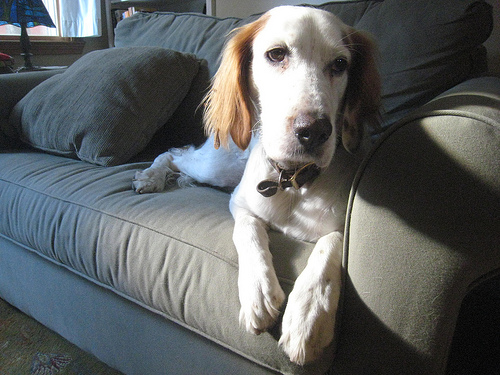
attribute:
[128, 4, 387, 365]
dog — staring, melancholy looking, white, sad looking, white-faced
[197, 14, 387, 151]
ears — floppy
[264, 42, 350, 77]
eyes — brown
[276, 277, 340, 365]
paw — dog's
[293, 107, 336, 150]
nose — dog's, brown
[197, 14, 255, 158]
ear — light brown, dog's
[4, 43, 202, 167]
pillow — grey, sofa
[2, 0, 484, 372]
sofa — grey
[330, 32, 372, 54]
whiskers — white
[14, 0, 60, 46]
cover — blue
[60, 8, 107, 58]
curtain — white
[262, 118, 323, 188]
collar — brown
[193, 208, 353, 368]
leg — brown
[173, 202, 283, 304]
leg — brown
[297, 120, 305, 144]
nostril — black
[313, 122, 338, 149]
nostril — black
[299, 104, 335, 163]
nostril — black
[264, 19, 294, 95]
eye — black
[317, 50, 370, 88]
eye — black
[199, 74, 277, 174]
ear — brown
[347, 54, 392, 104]
ear — brown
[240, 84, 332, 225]
dog — white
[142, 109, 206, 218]
leg — white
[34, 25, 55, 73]
window — bright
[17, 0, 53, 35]
lamp — blue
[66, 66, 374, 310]
lamp — blue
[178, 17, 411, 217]
dog — white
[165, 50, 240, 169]
ears — brown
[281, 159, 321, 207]
collar — brown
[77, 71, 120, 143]
couch — beige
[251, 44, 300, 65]
eye — brown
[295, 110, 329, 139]
nose — black